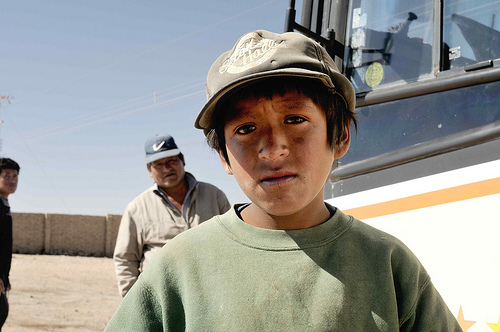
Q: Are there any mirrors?
A: Yes, there is a mirror.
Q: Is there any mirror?
A: Yes, there is a mirror.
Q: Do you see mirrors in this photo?
A: Yes, there is a mirror.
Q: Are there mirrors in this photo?
A: Yes, there is a mirror.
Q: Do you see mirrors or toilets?
A: Yes, there is a mirror.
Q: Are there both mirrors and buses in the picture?
A: Yes, there are both a mirror and a bus.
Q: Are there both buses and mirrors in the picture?
A: Yes, there are both a mirror and a bus.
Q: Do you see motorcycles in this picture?
A: No, there are no motorcycles.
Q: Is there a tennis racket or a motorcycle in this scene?
A: No, there are no motorcycles or rackets.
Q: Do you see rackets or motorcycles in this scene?
A: No, there are no motorcycles or rackets.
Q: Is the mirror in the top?
A: Yes, the mirror is in the top of the image.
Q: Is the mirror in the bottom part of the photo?
A: No, the mirror is in the top of the image.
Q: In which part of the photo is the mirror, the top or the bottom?
A: The mirror is in the top of the image.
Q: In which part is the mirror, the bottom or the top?
A: The mirror is in the top of the image.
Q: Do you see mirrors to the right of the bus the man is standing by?
A: No, the mirror is to the left of the bus.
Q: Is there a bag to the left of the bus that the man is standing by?
A: No, there is a mirror to the left of the bus.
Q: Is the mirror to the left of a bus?
A: Yes, the mirror is to the left of a bus.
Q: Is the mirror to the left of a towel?
A: No, the mirror is to the left of a bus.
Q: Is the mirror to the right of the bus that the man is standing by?
A: No, the mirror is to the left of the bus.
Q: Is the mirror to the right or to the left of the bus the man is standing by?
A: The mirror is to the left of the bus.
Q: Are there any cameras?
A: Yes, there is a camera.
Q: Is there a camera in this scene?
A: Yes, there is a camera.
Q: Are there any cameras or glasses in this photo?
A: Yes, there is a camera.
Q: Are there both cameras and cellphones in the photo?
A: No, there is a camera but no cell phones.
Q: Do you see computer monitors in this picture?
A: No, there are no computer monitors.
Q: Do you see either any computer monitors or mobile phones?
A: No, there are no computer monitors or mobile phones.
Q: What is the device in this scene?
A: The device is a camera.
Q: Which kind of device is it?
A: The device is a camera.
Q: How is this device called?
A: This is a camera.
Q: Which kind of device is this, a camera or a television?
A: This is a camera.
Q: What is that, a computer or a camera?
A: That is a camera.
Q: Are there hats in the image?
A: Yes, there is a hat.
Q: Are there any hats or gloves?
A: Yes, there is a hat.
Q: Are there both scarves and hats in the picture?
A: No, there is a hat but no scarves.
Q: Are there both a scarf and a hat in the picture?
A: No, there is a hat but no scarves.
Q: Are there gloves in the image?
A: No, there are no gloves.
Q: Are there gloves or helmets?
A: No, there are no gloves or helmets.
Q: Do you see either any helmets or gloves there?
A: No, there are no gloves or helmets.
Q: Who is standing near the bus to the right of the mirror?
A: The man is standing near the bus.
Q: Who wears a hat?
A: The man wears a hat.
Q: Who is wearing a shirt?
A: The man is wearing a shirt.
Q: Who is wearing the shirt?
A: The man is wearing a shirt.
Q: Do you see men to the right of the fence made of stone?
A: Yes, there is a man to the right of the fence.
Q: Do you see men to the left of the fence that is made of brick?
A: No, the man is to the right of the fence.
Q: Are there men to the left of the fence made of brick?
A: No, the man is to the right of the fence.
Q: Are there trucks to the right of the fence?
A: No, there is a man to the right of the fence.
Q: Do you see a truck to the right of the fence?
A: No, there is a man to the right of the fence.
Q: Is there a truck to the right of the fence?
A: No, there is a man to the right of the fence.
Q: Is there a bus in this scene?
A: Yes, there is a bus.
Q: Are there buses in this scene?
A: Yes, there is a bus.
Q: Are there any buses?
A: Yes, there is a bus.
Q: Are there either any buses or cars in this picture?
A: Yes, there is a bus.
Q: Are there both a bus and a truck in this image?
A: No, there is a bus but no trucks.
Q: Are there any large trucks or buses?
A: Yes, there is a large bus.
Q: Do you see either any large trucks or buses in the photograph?
A: Yes, there is a large bus.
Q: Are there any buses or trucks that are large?
A: Yes, the bus is large.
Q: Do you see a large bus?
A: Yes, there is a large bus.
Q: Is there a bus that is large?
A: Yes, there is a bus that is large.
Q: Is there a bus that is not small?
A: Yes, there is a large bus.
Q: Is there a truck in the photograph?
A: No, there are no trucks.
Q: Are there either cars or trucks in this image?
A: No, there are no trucks or cars.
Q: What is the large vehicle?
A: The vehicle is a bus.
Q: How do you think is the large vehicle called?
A: The vehicle is a bus.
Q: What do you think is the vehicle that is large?
A: The vehicle is a bus.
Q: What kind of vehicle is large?
A: The vehicle is a bus.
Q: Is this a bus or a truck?
A: This is a bus.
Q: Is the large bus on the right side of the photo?
A: Yes, the bus is on the right of the image.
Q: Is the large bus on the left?
A: No, the bus is on the right of the image.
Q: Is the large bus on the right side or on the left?
A: The bus is on the right of the image.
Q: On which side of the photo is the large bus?
A: The bus is on the right of the image.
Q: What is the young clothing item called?
A: The clothing item is a cap.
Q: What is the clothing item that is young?
A: The clothing item is a cap.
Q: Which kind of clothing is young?
A: The clothing is a cap.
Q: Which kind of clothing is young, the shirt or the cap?
A: The cap is young.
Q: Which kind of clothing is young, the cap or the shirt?
A: The cap is young.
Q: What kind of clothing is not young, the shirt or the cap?
A: The shirt is not young.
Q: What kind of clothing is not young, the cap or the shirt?
A: The shirt is not young.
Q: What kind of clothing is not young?
A: The clothing is a shirt.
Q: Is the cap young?
A: Yes, the cap is young.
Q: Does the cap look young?
A: Yes, the cap is young.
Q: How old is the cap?
A: The cap is young.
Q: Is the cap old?
A: No, the cap is young.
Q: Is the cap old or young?
A: The cap is young.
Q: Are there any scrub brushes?
A: No, there are no scrub brushes.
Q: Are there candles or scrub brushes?
A: No, there are no scrub brushes or candles.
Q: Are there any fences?
A: Yes, there is a fence.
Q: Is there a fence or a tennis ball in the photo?
A: Yes, there is a fence.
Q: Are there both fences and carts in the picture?
A: No, there is a fence but no carts.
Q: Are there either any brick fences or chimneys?
A: Yes, there is a brick fence.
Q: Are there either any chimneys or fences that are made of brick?
A: Yes, the fence is made of brick.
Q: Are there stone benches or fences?
A: Yes, there is a stone fence.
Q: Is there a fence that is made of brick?
A: Yes, there is a fence that is made of brick.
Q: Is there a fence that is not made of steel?
A: Yes, there is a fence that is made of brick.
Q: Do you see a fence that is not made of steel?
A: Yes, there is a fence that is made of brick.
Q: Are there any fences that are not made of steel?
A: Yes, there is a fence that is made of brick.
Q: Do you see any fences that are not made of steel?
A: Yes, there is a fence that is made of brick.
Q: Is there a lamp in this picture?
A: No, there are no lamps.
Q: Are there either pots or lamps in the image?
A: No, there are no lamps or pots.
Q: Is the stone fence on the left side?
A: Yes, the fence is on the left of the image.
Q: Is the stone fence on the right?
A: No, the fence is on the left of the image.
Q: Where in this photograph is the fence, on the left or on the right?
A: The fence is on the left of the image.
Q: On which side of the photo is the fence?
A: The fence is on the left of the image.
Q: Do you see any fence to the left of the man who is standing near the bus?
A: Yes, there is a fence to the left of the man.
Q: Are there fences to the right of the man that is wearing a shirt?
A: No, the fence is to the left of the man.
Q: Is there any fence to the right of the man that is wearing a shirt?
A: No, the fence is to the left of the man.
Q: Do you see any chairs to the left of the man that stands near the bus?
A: No, there is a fence to the left of the man.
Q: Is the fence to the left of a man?
A: Yes, the fence is to the left of a man.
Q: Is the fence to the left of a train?
A: No, the fence is to the left of a man.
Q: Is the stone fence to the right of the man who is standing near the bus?
A: No, the fence is to the left of the man.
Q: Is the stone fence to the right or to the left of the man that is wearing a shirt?
A: The fence is to the left of the man.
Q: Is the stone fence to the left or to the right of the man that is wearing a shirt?
A: The fence is to the left of the man.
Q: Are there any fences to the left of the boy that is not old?
A: Yes, there is a fence to the left of the boy.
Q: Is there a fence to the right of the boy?
A: No, the fence is to the left of the boy.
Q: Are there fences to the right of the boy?
A: No, the fence is to the left of the boy.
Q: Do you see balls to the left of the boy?
A: No, there is a fence to the left of the boy.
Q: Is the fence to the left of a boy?
A: Yes, the fence is to the left of a boy.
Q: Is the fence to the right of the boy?
A: No, the fence is to the left of the boy.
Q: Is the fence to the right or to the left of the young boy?
A: The fence is to the left of the boy.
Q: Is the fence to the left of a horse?
A: No, the fence is to the left of a man.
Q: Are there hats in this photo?
A: Yes, there is a hat.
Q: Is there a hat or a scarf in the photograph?
A: Yes, there is a hat.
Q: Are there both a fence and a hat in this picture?
A: Yes, there are both a hat and a fence.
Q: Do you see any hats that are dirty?
A: Yes, there is a dirty hat.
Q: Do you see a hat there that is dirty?
A: Yes, there is a hat that is dirty.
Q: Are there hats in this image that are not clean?
A: Yes, there is a dirty hat.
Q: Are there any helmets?
A: No, there are no helmets.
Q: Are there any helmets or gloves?
A: No, there are no helmets or gloves.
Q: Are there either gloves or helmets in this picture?
A: No, there are no helmets or gloves.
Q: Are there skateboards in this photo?
A: No, there are no skateboards.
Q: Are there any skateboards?
A: No, there are no skateboards.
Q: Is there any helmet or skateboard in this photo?
A: No, there are no skateboards or helmets.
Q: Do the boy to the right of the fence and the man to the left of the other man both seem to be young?
A: Yes, both the boy and the man are young.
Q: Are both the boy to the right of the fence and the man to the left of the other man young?
A: Yes, both the boy and the man are young.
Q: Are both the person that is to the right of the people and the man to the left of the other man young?
A: Yes, both the boy and the man are young.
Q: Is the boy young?
A: Yes, the boy is young.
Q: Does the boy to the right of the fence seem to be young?
A: Yes, the boy is young.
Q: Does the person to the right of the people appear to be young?
A: Yes, the boy is young.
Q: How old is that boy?
A: The boy is young.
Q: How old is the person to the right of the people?
A: The boy is young.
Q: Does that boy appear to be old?
A: No, the boy is young.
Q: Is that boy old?
A: No, the boy is young.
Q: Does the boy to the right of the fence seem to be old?
A: No, the boy is young.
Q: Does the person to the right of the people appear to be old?
A: No, the boy is young.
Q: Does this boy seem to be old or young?
A: The boy is young.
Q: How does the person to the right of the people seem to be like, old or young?
A: The boy is young.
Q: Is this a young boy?
A: Yes, this is a young boy.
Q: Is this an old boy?
A: No, this is a young boy.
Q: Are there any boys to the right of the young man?
A: Yes, there is a boy to the right of the man.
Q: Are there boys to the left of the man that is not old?
A: No, the boy is to the right of the man.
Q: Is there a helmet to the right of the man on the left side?
A: No, there is a boy to the right of the man.